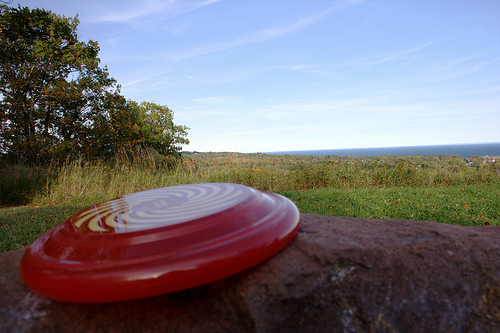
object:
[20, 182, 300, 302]
frisbee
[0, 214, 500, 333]
rock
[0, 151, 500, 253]
grass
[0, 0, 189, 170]
tree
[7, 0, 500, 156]
sky